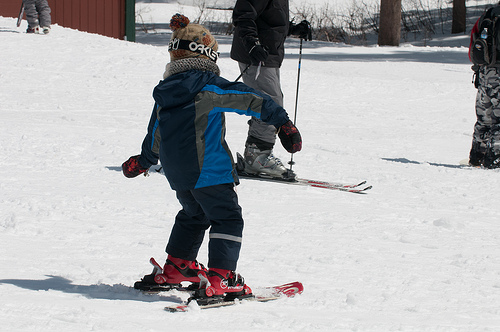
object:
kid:
[128, 7, 284, 303]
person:
[224, 5, 341, 195]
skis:
[135, 257, 310, 322]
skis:
[161, 270, 303, 312]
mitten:
[120, 150, 152, 179]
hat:
[154, 20, 216, 60]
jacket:
[135, 79, 256, 190]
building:
[50, 2, 140, 41]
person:
[225, 2, 360, 194]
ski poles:
[284, 25, 308, 109]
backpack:
[465, 12, 484, 62]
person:
[460, 4, 483, 153]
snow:
[2, 2, 484, 330]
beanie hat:
[164, 11, 221, 61]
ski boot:
[162, 251, 209, 284]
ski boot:
[205, 266, 253, 299]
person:
[468, 1, 483, 171]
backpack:
[468, 5, 484, 70]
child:
[119, 12, 302, 300]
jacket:
[138, 68, 288, 190]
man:
[229, 1, 314, 182]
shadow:
[2, 272, 189, 303]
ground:
[2, 2, 484, 330]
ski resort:
[1, 1, 484, 330]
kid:
[120, 11, 303, 296]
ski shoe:
[162, 250, 209, 281]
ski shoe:
[204, 265, 252, 300]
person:
[118, 11, 303, 299]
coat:
[138, 68, 288, 190]